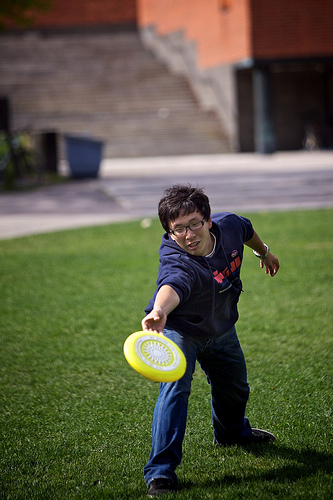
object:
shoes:
[147, 478, 174, 498]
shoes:
[212, 428, 277, 443]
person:
[130, 176, 281, 494]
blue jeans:
[209, 348, 248, 439]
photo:
[0, 36, 331, 500]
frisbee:
[57, 300, 197, 400]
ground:
[0, 188, 331, 499]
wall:
[137, 0, 255, 61]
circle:
[120, 328, 187, 382]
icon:
[244, 131, 296, 209]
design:
[136, 332, 181, 373]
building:
[130, 4, 320, 152]